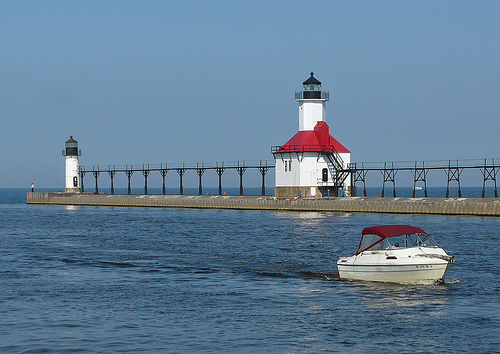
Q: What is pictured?
A: A boat and a lighthouse.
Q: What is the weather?
A: Sunny.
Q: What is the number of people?
A: Two.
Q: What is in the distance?
A: White and black light house.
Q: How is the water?
A: Blue and rippled.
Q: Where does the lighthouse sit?
A: A long pier.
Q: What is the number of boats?
A: One.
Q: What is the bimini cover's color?
A: Burgundy.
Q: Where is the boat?
A: In the water.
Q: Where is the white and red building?
A: On the pier.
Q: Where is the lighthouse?
A: On the end of the pier.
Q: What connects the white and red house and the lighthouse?
A: The pier.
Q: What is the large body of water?
A: Ocean.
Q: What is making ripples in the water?
A: The boat.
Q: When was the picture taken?
A: In the morning.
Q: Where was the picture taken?
A: A beach.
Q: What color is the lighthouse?
A: Black and white.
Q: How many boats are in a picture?
A: One.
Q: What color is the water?
A: Blue.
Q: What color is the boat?
A: Red and white.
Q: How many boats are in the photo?
A: One.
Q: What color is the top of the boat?
A: Red.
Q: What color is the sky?
A: Blue.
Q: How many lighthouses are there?
A: Two.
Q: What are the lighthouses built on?
A: A dock.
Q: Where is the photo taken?
A: On a body of water.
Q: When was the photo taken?
A: During the day.